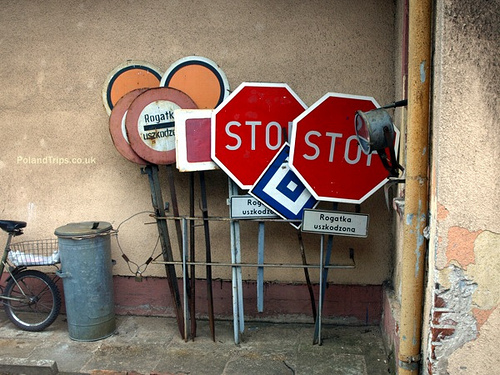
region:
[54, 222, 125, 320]
Trash can next to a bike.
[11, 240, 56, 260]
Basket on bike.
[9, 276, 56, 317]
Wheel of the bike.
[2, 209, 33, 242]
Seat of the bike.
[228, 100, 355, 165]
Two stops signs against a building.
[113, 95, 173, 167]
Round red and white signs.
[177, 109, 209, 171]
Rectangular white and red signs.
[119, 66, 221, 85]
Circular orange. white and black signs.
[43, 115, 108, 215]
Side of the building.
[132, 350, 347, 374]
Sidewalk in front of the building.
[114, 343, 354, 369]
Gray concrete floor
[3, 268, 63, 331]
Rear wheel of the bicycle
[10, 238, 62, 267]
Basket attached to the bicycle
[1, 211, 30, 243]
Black bicycle seat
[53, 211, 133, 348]
Gray cylindrical trash can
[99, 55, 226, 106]
Two white, black and orange signs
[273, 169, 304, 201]
Blue diamond in the center of the blue and white sign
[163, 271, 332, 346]
Posts of all the signs resting on the ground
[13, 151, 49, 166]
The word Poland in the writing on the wall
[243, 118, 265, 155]
The T in the stop sign in the middle of the group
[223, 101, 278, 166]
a red stop sign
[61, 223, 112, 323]
a dark blue trash bin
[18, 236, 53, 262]
basket on back of bike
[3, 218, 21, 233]
black bicycle seat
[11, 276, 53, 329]
a black bicycle wheel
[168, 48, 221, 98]
an orange and white circle sign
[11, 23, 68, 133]
a light brown wall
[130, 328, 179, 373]
a dark silver street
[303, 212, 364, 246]
a white sign with foreign language on it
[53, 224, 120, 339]
this is a trashcan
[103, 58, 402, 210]
roadsigns disposed off in a corner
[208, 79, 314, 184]
red stop sign not on a road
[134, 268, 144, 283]
this is a padlock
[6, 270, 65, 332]
this is a bicycle wheel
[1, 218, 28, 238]
this is a bicycle seat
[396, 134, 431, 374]
this is a drainage pipe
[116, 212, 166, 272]
chainlink padlock made of a connecting wire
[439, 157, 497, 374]
this is part of wall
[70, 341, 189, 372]
this is part of a pavement for walking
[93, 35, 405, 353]
Ten signs leaning on a wall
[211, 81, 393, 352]
Two STOP signs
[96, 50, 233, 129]
Two orange signs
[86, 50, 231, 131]
Orange signs are round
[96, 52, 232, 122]
Orange signs have white border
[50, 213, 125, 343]
Trash can next to a bike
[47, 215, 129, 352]
Trash can is metal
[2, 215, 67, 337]
Bike next to trash can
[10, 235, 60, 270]
Bike basket close to trash can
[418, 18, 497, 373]
Wall is damaged